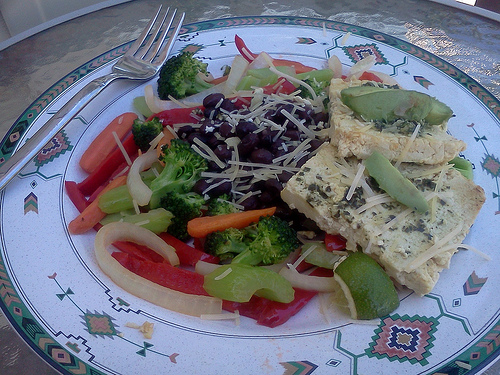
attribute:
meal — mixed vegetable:
[57, 32, 492, 325]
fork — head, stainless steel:
[1, 0, 185, 186]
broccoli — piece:
[230, 211, 302, 270]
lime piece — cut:
[333, 249, 404, 322]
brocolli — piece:
[151, 39, 211, 96]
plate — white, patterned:
[334, 17, 479, 124]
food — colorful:
[68, 22, 490, 324]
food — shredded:
[64, 37, 485, 310]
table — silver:
[5, 3, 484, 120]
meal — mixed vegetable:
[100, 34, 474, 328]